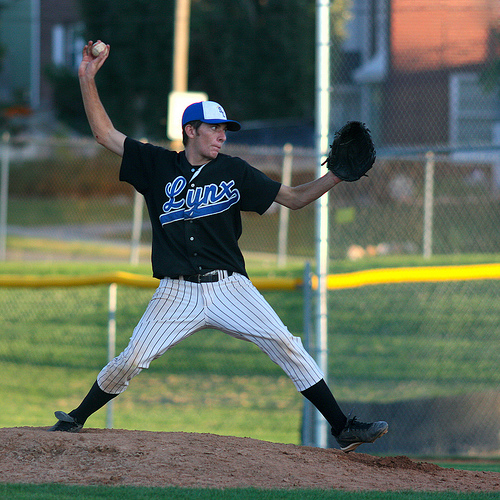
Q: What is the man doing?
A: Pitching a baseball.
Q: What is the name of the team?
A: Lynx.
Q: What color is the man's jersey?
A: Black.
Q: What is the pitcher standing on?
A: The mound.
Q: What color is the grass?
A: Green.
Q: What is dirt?
A: Pitching mound.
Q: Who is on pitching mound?
A: Player.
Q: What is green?
A: Grass.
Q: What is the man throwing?
A: Ball.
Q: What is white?
A: Pants.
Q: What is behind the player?
A: Fence.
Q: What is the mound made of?
A: Dirt.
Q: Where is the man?
A: On pitcher's mound.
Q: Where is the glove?
A: On man's left hand.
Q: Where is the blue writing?
A: On man's jersey.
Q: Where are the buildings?
A: Background.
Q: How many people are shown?
A: 1.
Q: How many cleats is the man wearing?
A: 2.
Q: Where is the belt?
A: On man's pants.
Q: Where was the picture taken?
A: In a baseball field.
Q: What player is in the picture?
A: The pitcher.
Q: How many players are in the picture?
A: 1.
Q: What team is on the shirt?
A: Lynx.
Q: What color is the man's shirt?
A: Black.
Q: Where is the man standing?
A: Pitcher's mound.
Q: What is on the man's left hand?
A: A glove.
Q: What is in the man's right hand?
A: A baseball.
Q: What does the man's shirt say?
A: Lynx.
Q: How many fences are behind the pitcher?
A: Two.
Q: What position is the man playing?
A: Pitcher.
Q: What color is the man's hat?
A: Blue and white.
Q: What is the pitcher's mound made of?
A: Dirt.